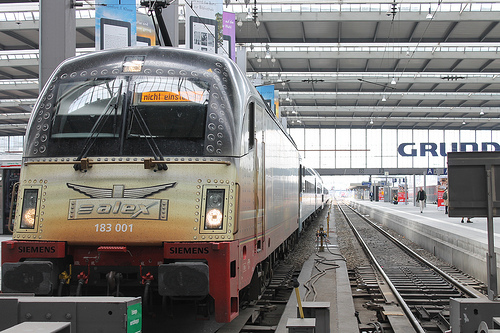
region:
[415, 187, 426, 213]
man walking in a black jacket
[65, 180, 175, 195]
wings on the front of the bus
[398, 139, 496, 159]
GRUDD in black letters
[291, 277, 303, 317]
yellow pole with black on top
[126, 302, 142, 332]
green sign with white letters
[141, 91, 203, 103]
yellow sign reflectied in wondow of train with black letters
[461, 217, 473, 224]
feet in black shoes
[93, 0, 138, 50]
blue sign with smart phone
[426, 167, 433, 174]
blue sign with white A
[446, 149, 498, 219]
back of metal sign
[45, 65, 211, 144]
front window of train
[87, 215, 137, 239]
white numbers painted on train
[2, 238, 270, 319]
red bottom of train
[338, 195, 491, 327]
unused train tracks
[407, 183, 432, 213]
man walking train platform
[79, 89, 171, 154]
black windshield wipers on train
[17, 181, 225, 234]
front headlight of the train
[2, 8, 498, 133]
roof above train on tracks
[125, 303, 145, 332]
green stick with white lettering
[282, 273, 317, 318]
yellow pole with black top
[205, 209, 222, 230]
Headlights in the photo.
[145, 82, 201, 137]
Windscreen of a train.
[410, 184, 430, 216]
A man in the photo.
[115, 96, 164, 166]
Wipers in the photo.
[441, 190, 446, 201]
A black bag in the photo.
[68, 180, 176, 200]
An eagle logo in the photo.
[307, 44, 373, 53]
Lightings in the photo.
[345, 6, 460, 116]
Roof in the photo.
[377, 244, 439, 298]
Rail line in the photo.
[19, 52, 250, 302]
A train in the photo.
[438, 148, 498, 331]
metal plate attached to train tracks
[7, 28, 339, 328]
long orange train parked in station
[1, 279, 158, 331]
metal structure at the end of train tracks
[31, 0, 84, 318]
square metal beam supporting train station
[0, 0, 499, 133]
gray metal train station roof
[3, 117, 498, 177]
large clear windows on train station wall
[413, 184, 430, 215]
man walking on concrete train station platform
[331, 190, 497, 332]
long metal train tracks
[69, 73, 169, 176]
black windshield wipers on train windows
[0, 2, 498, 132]
rows of bright white lights attached to roof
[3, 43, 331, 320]
a train on the tracks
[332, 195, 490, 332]
train tracks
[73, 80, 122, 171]
a wiper on a windshield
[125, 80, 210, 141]
a window on the front of a train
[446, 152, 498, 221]
a sign on a pole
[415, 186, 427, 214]
a man walking on a train platform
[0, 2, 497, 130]
a ceiling of metal and glass at a train station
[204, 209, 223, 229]
a headlight on a train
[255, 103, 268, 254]
a door on a train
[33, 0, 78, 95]
a metal pillar in a train station